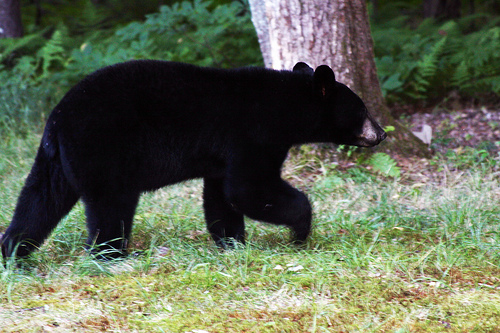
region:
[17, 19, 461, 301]
a bear walking through the woods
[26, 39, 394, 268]
a big black bear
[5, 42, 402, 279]
the balck bear is furry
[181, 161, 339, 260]
the bear's legs is bent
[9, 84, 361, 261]
the bear is on the move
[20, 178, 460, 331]
grass beneath the bear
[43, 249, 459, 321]
the grass is sparse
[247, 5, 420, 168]
a tree trunk behind the bear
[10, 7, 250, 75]
green vegetation near the bear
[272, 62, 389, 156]
this is the bear's face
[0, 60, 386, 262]
A black bear walking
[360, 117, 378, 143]
Light colored patch on the side of the bears face.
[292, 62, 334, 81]
Two black furry ears on a bears head.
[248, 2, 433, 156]
A thick brown tree trunk.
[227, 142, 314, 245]
Front right bent arm of a bear.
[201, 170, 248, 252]
A black left bear arm.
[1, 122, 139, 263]
Two back bear legs that are black.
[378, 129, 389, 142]
Black nose of a bear.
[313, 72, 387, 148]
Head and snout of a bear.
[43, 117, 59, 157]
A small black furry tail of a bear.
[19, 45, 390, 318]
a bear walking outside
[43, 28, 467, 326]
a black bear walking outside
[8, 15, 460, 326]
a bear that is outside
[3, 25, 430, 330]
a black bear that is outside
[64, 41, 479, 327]
a bear on all fours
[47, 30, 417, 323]
a black bear on all fours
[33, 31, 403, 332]
a bear in a field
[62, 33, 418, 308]
a black bear in a field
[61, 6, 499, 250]
a bear walking on grass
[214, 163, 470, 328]
a field of grass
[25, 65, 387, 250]
A black bear on the prowl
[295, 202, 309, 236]
Paw raised up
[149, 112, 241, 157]
Black fur on the bear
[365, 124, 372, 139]
Light color on the snout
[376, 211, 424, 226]
Green grass under the bear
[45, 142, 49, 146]
A white spot on the tail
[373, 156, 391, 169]
A fern in the grass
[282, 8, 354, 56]
The trunk of a tree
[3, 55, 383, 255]
a bear walking through the woods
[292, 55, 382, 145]
the head of a black bear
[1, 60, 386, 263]
black bear walking through the woods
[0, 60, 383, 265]
black bear ambulating in the woods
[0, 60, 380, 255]
bear ambulating in the woods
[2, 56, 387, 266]
bear in grassy area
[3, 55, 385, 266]
black bear in a grassy area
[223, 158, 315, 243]
bent front right leg of a bear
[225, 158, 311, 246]
right front leg of a black bear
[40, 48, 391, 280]
big bear on the grass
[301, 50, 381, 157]
black head of the bear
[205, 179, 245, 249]
furry black left leg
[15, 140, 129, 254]
rear leg of the bear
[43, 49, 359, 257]
bear walking on the grass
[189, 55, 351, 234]
bear walking on the ground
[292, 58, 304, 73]
letf ear of the bear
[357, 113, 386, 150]
the nose on the bear isbrown